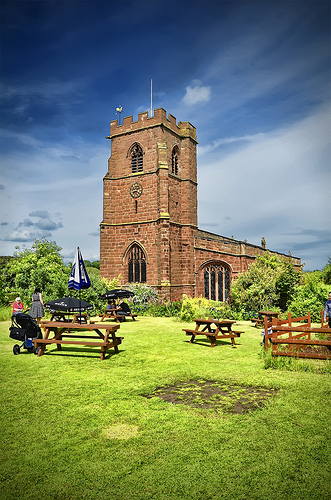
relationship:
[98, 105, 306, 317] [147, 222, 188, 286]
building has bricks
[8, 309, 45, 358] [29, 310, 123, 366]
stroller beside table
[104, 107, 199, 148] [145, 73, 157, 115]
roof has pole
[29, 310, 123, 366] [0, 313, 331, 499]
table on grass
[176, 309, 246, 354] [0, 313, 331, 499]
table on grass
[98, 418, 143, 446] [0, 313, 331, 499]
spot in grass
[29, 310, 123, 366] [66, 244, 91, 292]
table with umbrella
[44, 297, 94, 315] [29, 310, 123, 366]
umbrella over table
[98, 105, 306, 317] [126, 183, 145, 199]
building has clock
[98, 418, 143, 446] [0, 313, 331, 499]
spot on grass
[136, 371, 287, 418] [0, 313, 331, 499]
patch on grass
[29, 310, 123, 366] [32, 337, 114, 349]
table has bench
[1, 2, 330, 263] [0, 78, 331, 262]
sky has clouds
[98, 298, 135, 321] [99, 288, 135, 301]
people beneath umbrella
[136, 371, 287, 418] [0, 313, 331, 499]
patch in grass